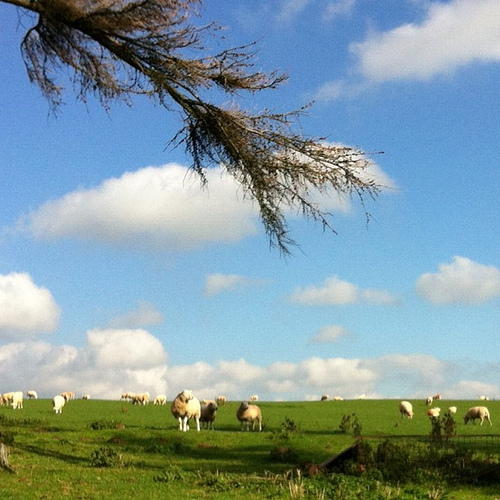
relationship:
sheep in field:
[2, 379, 495, 434] [2, 397, 499, 499]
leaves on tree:
[2, 0, 404, 264] [0, 0, 404, 268]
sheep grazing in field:
[129, 383, 271, 434] [2, 397, 499, 499]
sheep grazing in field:
[235, 397, 262, 430] [2, 397, 499, 499]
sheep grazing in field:
[398, 397, 413, 419] [2, 397, 499, 499]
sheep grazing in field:
[458, 405, 493, 427] [2, 397, 499, 499]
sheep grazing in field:
[169, 387, 204, 433] [2, 397, 499, 499]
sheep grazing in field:
[49, 395, 69, 412] [2, 397, 499, 499]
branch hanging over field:
[0, 0, 394, 259] [2, 397, 499, 499]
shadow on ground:
[115, 433, 498, 485] [2, 399, 497, 499]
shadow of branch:
[115, 433, 498, 485] [7, 2, 394, 257]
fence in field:
[360, 426, 494, 489] [17, 409, 486, 490]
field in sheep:
[2, 397, 499, 499] [166, 388, 266, 432]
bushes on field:
[298, 401, 378, 461] [12, 365, 458, 496]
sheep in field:
[168, 358, 218, 453] [273, 438, 444, 481]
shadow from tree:
[0, 422, 499, 486] [8, 2, 428, 255]